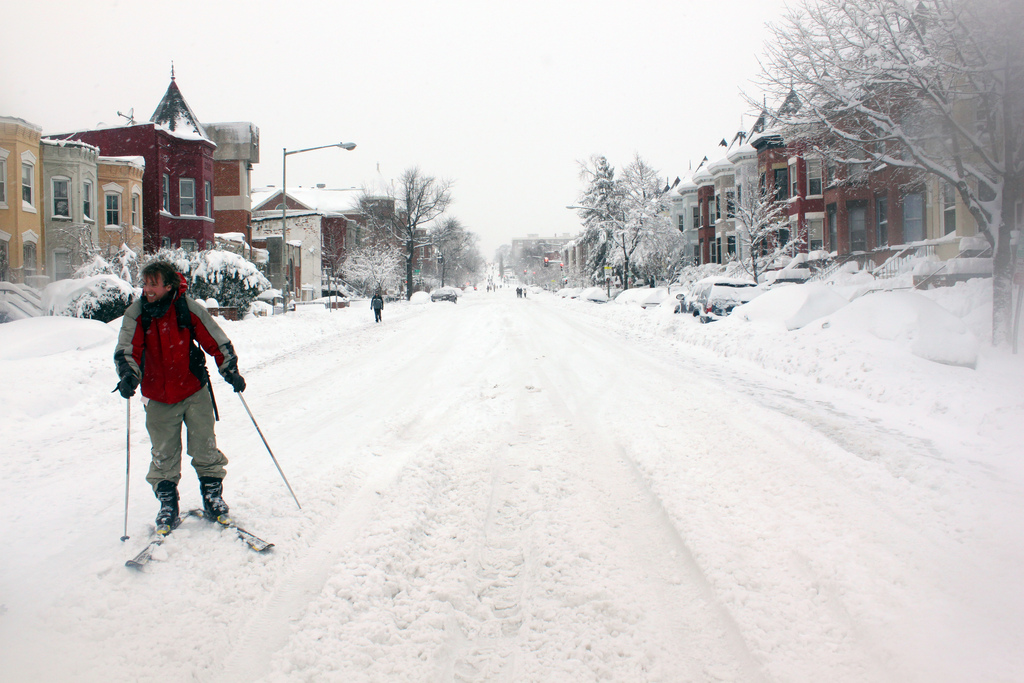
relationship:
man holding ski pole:
[102, 259, 321, 579] [109, 386, 144, 545]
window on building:
[43, 173, 75, 224] [42, 134, 106, 286]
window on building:
[802, 150, 828, 201] [104, 107, 381, 376]